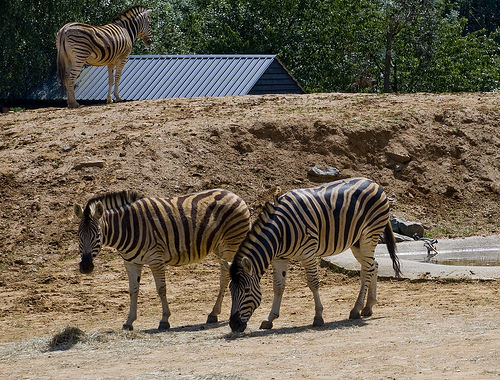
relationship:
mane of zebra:
[79, 189, 140, 214] [73, 188, 251, 329]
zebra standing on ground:
[45, 0, 161, 110] [0, 90, 498, 360]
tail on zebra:
[379, 215, 407, 282] [223, 176, 403, 333]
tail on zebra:
[379, 215, 404, 281] [206, 190, 375, 329]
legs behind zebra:
[114, 256, 181, 334] [63, 178, 255, 328]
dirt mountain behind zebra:
[1, 90, 493, 320] [223, 176, 403, 333]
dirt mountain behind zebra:
[1, 90, 493, 320] [73, 188, 251, 329]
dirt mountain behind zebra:
[1, 90, 493, 320] [56, 2, 159, 104]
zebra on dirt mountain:
[56, 2, 159, 104] [1, 90, 500, 380]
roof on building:
[31, 31, 311, 105] [23, 54, 309, 109]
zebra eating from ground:
[206, 167, 401, 352] [0, 90, 498, 360]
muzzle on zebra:
[224, 302, 273, 348] [219, 157, 438, 371]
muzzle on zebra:
[76, 234, 95, 280] [65, 176, 264, 339]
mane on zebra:
[78, 189, 144, 242] [73, 188, 251, 329]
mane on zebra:
[109, 2, 146, 22] [56, 2, 159, 104]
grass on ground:
[1, 325, 152, 356] [15, 316, 458, 377]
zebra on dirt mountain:
[48, 4, 153, 109] [1, 90, 500, 380]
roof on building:
[27, 52, 307, 102] [23, 52, 311, 108]